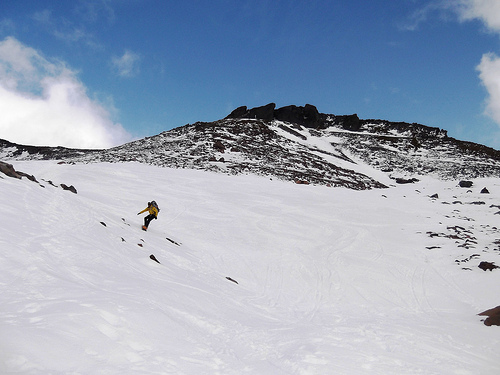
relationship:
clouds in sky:
[0, 30, 143, 181] [0, 0, 498, 152]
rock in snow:
[1, 156, 21, 179] [283, 264, 452, 357]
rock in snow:
[144, 251, 166, 269] [65, 270, 199, 372]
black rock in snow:
[223, 275, 240, 283] [0, 157, 499, 373]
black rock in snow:
[164, 235, 179, 244] [9, 167, 472, 367]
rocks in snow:
[420, 222, 480, 272] [0, 122, 499, 373]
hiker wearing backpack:
[137, 201, 160, 231] [149, 187, 159, 210]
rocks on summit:
[224, 100, 359, 133] [122, 99, 498, 192]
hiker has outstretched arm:
[137, 201, 160, 231] [134, 205, 148, 216]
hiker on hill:
[137, 201, 160, 231] [0, 105, 498, 370]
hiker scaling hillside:
[137, 201, 160, 231] [4, 143, 499, 373]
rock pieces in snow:
[99, 217, 236, 282] [0, 157, 499, 373]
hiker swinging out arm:
[137, 201, 160, 231] [136, 207, 149, 215]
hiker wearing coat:
[137, 201, 160, 231] [118, 178, 190, 262]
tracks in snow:
[215, 277, 382, 329] [139, 189, 430, 331]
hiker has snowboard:
[137, 201, 160, 231] [128, 220, 163, 236]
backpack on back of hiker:
[151, 200, 160, 210] [137, 201, 160, 231]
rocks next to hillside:
[429, 213, 496, 293] [0, 161, 499, 372]